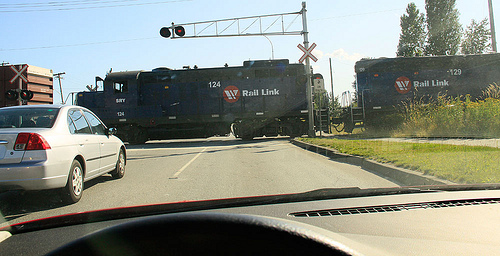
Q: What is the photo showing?
A: It is showing a street.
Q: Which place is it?
A: It is a street.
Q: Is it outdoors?
A: Yes, it is outdoors.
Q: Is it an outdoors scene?
A: Yes, it is outdoors.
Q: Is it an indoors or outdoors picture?
A: It is outdoors.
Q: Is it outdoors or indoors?
A: It is outdoors.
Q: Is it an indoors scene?
A: No, it is outdoors.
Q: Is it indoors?
A: No, it is outdoors.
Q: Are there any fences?
A: No, there are no fences.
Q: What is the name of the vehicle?
A: The vehicle is a car.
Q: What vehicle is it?
A: The vehicle is a car.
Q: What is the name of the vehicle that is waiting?
A: The vehicle is a car.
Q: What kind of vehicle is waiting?
A: The vehicle is a car.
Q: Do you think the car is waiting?
A: Yes, the car is waiting.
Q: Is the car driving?
A: No, the car is waiting.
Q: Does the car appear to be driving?
A: No, the car is waiting.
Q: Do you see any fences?
A: No, there are no fences.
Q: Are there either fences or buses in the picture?
A: No, there are no fences or buses.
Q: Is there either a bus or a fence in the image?
A: No, there are no fences or buses.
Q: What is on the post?
A: The sign is on the post.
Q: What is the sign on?
A: The sign is on the post.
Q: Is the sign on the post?
A: Yes, the sign is on the post.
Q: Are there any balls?
A: No, there are no balls.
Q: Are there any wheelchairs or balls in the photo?
A: No, there are no balls or wheelchairs.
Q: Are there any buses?
A: No, there are no buses.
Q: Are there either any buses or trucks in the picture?
A: No, there are no buses or trucks.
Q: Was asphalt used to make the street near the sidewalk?
A: Yes, the street is made of asphalt.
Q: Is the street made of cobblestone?
A: No, the street is made of asphalt.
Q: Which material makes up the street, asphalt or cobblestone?
A: The street is made of asphalt.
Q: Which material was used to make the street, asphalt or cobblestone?
A: The street is made of asphalt.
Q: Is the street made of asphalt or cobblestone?
A: The street is made of asphalt.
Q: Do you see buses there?
A: No, there are no buses.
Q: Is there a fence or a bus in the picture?
A: No, there are no buses or fences.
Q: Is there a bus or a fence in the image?
A: No, there are no buses or fences.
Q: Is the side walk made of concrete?
A: Yes, the side walk is made of concrete.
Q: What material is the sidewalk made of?
A: The sidewalk is made of cement.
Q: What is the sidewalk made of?
A: The sidewalk is made of concrete.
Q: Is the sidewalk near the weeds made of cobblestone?
A: No, the sidewalk is made of concrete.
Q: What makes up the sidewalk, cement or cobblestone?
A: The sidewalk is made of cement.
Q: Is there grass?
A: Yes, there is grass.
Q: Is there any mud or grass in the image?
A: Yes, there is grass.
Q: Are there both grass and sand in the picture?
A: No, there is grass but no sand.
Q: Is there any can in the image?
A: No, there are no cans.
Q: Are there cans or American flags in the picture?
A: No, there are no cans or American flags.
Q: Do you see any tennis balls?
A: No, there are no tennis balls.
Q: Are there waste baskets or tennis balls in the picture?
A: No, there are no tennis balls or waste baskets.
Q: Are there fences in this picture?
A: No, there are no fences.